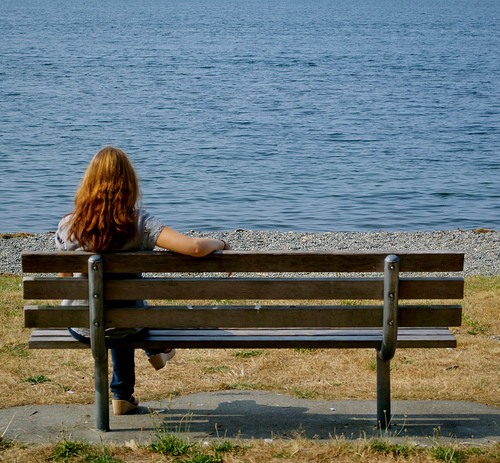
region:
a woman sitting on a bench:
[19, 132, 494, 394]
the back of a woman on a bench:
[46, 137, 244, 442]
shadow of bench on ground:
[142, 381, 499, 461]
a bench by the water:
[21, 163, 463, 398]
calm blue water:
[3, 7, 498, 207]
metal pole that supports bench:
[60, 258, 134, 430]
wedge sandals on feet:
[153, 346, 188, 383]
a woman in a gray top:
[43, 198, 185, 352]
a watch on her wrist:
[213, 238, 228, 258]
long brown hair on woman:
[65, 135, 171, 300]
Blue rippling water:
[244, 71, 406, 183]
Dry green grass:
[436, 358, 498, 398]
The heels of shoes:
[109, 377, 143, 419]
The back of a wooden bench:
[267, 248, 464, 355]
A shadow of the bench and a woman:
[175, 397, 382, 438]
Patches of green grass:
[146, 433, 246, 462]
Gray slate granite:
[329, 228, 483, 254]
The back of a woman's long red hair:
[69, 142, 145, 254]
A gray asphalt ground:
[9, 410, 90, 437]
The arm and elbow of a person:
[167, 227, 234, 259]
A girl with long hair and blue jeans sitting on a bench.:
[54, 143, 235, 408]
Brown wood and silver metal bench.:
[21, 249, 468, 433]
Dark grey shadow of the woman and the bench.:
[161, 400, 499, 442]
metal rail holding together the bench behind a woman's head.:
[83, 252, 110, 432]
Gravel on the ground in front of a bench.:
[2, 231, 497, 271]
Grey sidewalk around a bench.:
[3, 389, 498, 444]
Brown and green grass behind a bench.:
[2, 438, 499, 460]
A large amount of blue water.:
[1, 0, 498, 230]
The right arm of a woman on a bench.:
[155, 228, 230, 257]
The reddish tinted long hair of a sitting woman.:
[72, 143, 137, 250]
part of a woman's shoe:
[150, 347, 177, 370]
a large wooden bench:
[16, 248, 466, 428]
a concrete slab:
[0, 388, 498, 448]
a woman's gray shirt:
[51, 205, 161, 338]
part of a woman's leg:
[107, 342, 139, 397]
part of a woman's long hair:
[57, 145, 143, 257]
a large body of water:
[0, 3, 497, 230]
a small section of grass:
[152, 423, 188, 455]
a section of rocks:
[395, 228, 499, 273]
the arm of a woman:
[156, 226, 223, 258]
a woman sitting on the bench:
[29, 121, 243, 378]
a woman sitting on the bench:
[26, 106, 369, 445]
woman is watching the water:
[66, 123, 252, 420]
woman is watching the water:
[22, 65, 330, 435]